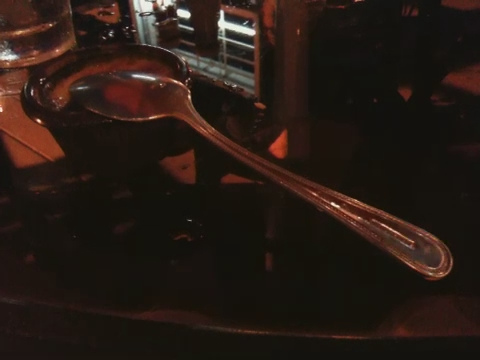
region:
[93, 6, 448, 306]
large silver spoon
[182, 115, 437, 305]
handle of large silver spoon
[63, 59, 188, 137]
scooping portion of silver spoon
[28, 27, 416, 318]
spoon resting on a small bowl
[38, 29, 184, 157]
small bowl of dipping sauce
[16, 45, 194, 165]
black bowl of sauce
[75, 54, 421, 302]
spoon and small bowl on table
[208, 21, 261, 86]
metal racks in background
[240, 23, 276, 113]
metal frame next to racks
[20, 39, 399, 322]
table with spoon on it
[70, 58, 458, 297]
a steel spoon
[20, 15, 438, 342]
dark place with utensils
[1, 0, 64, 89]
water can with full of water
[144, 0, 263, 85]
window of the kitchen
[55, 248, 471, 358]
brown colour dining table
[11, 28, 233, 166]
a cup with a spoon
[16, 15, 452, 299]
a steel spoon and cup near the water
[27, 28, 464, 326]
dark place with some utensils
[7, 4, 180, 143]
water can near the cup and spoon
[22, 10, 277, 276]
a cup kept in the dining table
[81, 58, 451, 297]
silver spoon resting on dish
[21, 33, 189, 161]
black dish holding liquid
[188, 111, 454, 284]
silver handle of spoon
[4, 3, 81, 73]
glass in upper corner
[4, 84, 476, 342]
black countertop spoon is on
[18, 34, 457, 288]
spoon and dish it's resting on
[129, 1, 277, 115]
lit up display behind spoon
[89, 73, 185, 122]
reflection on silver spoon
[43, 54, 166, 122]
sauce in black dish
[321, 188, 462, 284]
portion of spoon resting on counter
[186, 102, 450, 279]
the handle of a silver spoon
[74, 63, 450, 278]
a silver metal spoon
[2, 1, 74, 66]
the bottom a clear glass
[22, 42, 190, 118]
a brown ceramic small dish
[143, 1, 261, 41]
a long white light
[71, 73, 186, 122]
the spoon head of the spoon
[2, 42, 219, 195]
a wooden table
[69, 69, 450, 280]
the upside down spoon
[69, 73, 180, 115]
the black tarnish of a spoon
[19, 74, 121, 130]
the edge of the dish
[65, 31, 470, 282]
a spoon on a table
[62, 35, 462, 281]
spoon is color silver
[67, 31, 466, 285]
spoon is dirty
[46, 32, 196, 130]
black spots on spoon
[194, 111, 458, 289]
handle of spoon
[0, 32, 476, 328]
spoon on a brown table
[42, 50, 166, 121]
brown cream on spoon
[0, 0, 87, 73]
a glass in front a spoon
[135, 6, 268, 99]
a window with frame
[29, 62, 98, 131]
brown cream spills on tabel